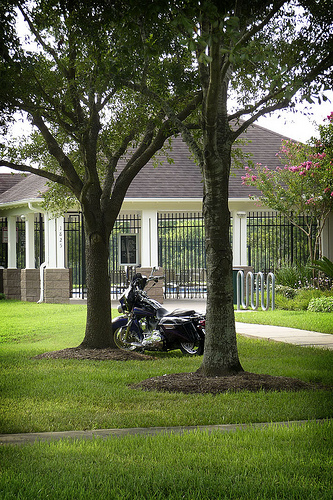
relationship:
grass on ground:
[8, 298, 229, 486] [0, 294, 332, 499]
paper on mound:
[142, 366, 182, 400] [135, 360, 305, 408]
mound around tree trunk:
[135, 360, 305, 408] [75, 3, 331, 382]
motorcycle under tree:
[117, 263, 212, 353] [45, 2, 333, 374]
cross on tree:
[82, 230, 113, 250] [2, 0, 190, 351]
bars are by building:
[63, 210, 318, 305] [1, 95, 333, 306]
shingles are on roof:
[150, 158, 218, 203] [0, 96, 332, 202]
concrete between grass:
[165, 292, 332, 363] [2, 301, 332, 499]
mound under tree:
[135, 360, 305, 408] [45, 2, 333, 374]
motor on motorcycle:
[112, 287, 157, 316] [117, 263, 212, 353]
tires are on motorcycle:
[115, 317, 216, 357] [117, 263, 212, 353]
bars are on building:
[63, 210, 318, 305] [1, 95, 333, 306]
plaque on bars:
[119, 230, 148, 268] [63, 210, 318, 305]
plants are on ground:
[263, 271, 333, 318] [0, 294, 332, 499]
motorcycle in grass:
[117, 263, 212, 353] [8, 298, 229, 486]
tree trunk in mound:
[75, 3, 331, 382] [135, 360, 305, 408]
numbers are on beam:
[54, 217, 72, 254] [49, 221, 67, 274]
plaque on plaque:
[121, 236, 135, 263] [119, 230, 148, 268]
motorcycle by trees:
[117, 263, 212, 353] [4, 2, 331, 403]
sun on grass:
[5, 298, 102, 347] [8, 298, 229, 486]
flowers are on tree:
[243, 147, 331, 192] [244, 112, 332, 280]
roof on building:
[0, 96, 332, 202] [1, 95, 333, 306]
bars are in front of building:
[63, 210, 318, 305] [1, 95, 333, 306]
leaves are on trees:
[42, 14, 249, 98] [4, 2, 331, 403]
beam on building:
[49, 221, 67, 274] [1, 95, 333, 306]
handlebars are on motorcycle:
[121, 260, 171, 310] [117, 263, 212, 353]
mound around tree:
[135, 360, 305, 408] [45, 2, 333, 374]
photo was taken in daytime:
[1, 1, 333, 498] [0, 2, 329, 499]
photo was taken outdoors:
[1, 1, 333, 498] [2, 2, 332, 498]